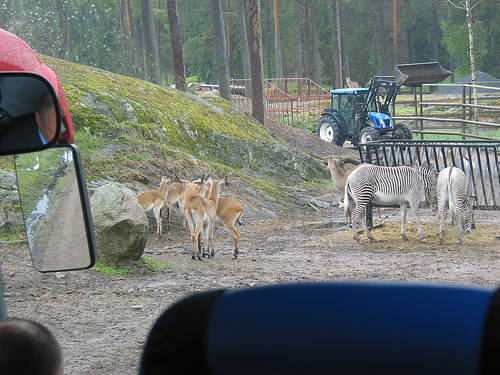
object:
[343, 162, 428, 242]
zebra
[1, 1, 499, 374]
scene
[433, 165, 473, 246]
zebra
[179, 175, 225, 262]
antelope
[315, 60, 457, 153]
tractor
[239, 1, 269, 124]
tree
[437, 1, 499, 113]
tree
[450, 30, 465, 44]
leaves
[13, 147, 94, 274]
mirror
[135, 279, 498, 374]
chair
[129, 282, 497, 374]
back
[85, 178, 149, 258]
rock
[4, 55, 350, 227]
moss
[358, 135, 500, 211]
feeder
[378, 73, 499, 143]
fence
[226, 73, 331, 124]
metal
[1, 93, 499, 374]
ground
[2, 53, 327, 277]
grass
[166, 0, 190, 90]
tree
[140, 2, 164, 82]
tree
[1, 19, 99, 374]
vehicle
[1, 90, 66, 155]
man